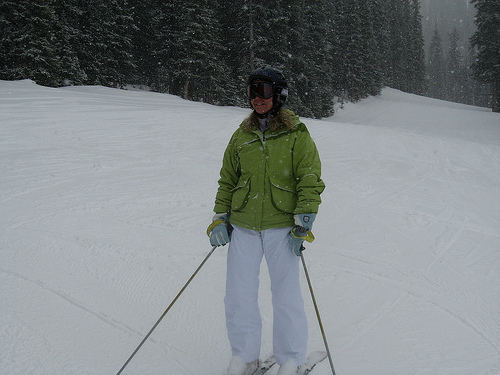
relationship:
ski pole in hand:
[297, 253, 364, 374] [287, 221, 320, 257]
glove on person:
[204, 218, 236, 244] [202, 67, 327, 323]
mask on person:
[244, 82, 279, 101] [202, 67, 327, 323]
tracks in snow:
[377, 244, 434, 317] [343, 161, 455, 327]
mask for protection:
[247, 82, 279, 114] [436, 17, 437, 24]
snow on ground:
[343, 161, 455, 327] [352, 110, 445, 221]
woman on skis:
[202, 67, 327, 323] [218, 345, 330, 371]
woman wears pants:
[202, 67, 327, 323] [231, 218, 308, 358]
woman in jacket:
[202, 67, 327, 323] [208, 111, 327, 215]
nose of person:
[254, 96, 261, 101] [202, 67, 327, 323]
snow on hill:
[343, 161, 455, 327] [360, 62, 462, 227]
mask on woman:
[244, 82, 279, 101] [202, 67, 327, 323]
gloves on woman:
[209, 211, 315, 254] [202, 67, 327, 323]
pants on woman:
[231, 218, 308, 358] [202, 67, 327, 323]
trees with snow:
[149, 4, 236, 85] [343, 161, 455, 327]